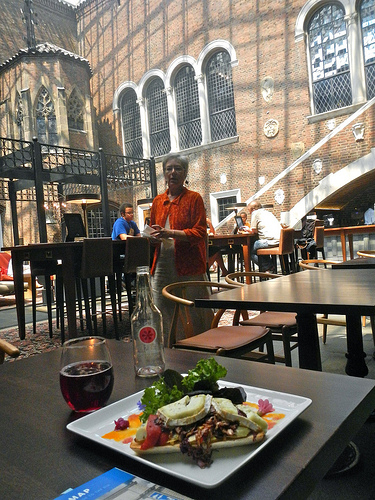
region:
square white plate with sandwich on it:
[65, 365, 311, 490]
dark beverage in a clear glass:
[57, 330, 117, 415]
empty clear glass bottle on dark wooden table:
[123, 263, 171, 381]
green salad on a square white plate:
[140, 357, 230, 398]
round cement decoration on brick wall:
[253, 118, 283, 138]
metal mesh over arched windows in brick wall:
[113, 42, 245, 163]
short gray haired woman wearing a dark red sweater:
[125, 146, 218, 344]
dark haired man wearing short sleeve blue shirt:
[106, 201, 145, 248]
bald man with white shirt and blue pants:
[240, 195, 292, 263]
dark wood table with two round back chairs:
[161, 251, 371, 368]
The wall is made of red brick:
[91, 3, 289, 43]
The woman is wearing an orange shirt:
[136, 156, 224, 284]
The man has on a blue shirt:
[111, 205, 141, 240]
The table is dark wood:
[5, 381, 70, 484]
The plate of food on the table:
[64, 355, 314, 496]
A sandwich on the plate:
[127, 382, 279, 447]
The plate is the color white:
[69, 410, 270, 498]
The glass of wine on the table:
[54, 332, 117, 415]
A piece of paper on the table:
[40, 461, 209, 497]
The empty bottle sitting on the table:
[128, 261, 168, 378]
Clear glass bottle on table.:
[123, 261, 165, 376]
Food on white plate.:
[69, 371, 309, 489]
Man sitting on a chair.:
[247, 197, 295, 269]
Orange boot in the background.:
[0, 244, 13, 285]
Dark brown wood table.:
[193, 268, 373, 310]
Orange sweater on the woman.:
[139, 149, 214, 337]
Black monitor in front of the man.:
[233, 214, 246, 233]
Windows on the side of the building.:
[107, 35, 241, 165]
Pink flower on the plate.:
[253, 396, 276, 415]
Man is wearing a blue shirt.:
[110, 202, 138, 241]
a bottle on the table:
[128, 262, 169, 372]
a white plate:
[192, 459, 217, 486]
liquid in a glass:
[72, 370, 106, 407]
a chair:
[163, 283, 244, 353]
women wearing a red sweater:
[174, 196, 203, 231]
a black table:
[13, 390, 51, 457]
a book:
[93, 475, 144, 496]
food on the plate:
[120, 403, 261, 448]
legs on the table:
[295, 317, 331, 360]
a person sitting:
[248, 202, 279, 247]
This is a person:
[145, 145, 216, 343]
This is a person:
[112, 195, 144, 255]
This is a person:
[246, 188, 289, 271]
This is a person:
[230, 206, 251, 252]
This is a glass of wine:
[53, 322, 122, 427]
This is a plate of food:
[114, 363, 310, 479]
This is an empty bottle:
[129, 261, 172, 385]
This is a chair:
[151, 272, 288, 364]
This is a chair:
[227, 260, 318, 381]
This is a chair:
[292, 245, 363, 332]